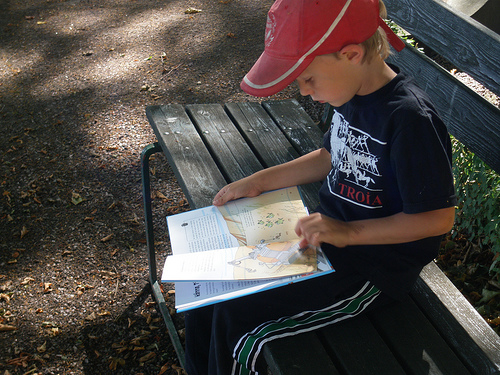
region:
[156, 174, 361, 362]
Book in a boys hands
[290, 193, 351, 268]
Hand on a book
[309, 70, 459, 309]
Shirt on a boy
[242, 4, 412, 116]
Red hat on a head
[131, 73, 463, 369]
Brown bench under a boy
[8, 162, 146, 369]
Leaves on the ground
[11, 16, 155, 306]
Brown leaf covered ground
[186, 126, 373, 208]
Arm on a boy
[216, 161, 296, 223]
Hand on a boy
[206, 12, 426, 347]
Boy on a bench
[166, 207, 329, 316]
a book holding by a boy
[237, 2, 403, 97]
a cap wearing by a small boy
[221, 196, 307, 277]
a art design inside the book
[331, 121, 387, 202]
design drawn in the shirt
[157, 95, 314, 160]
a wooden bench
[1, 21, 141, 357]
sand on the ground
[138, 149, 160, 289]
iron road holding the bench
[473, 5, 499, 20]
a small portion of tree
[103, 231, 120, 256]
flower fallen down from tree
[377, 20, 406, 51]
back lock of cap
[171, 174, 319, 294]
a book holding by boy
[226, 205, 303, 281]
an art design inside the books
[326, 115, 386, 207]
an design on the boys shirt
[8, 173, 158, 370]
sand on down of park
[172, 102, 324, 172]
wooden bench in the park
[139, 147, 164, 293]
a supporting stand of bench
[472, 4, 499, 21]
small portion of a tree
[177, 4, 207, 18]
a small stone in the sand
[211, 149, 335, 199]
hand of a small boy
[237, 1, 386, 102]
cap of the boy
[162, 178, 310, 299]
a book holding by the boy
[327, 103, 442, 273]
tshirt wearing by the boy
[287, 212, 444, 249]
left hand of the boy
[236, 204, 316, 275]
an art design in side the book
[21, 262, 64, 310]
flowers fallen from tree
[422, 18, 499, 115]
a wooden bench in the park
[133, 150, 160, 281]
supporting iron rod of the bench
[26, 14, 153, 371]
sand in the park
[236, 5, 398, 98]
cap wearing by the boy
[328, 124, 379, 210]
quotation on the boy tshirt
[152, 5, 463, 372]
young boy sitting on a bench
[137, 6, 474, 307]
young boy reading a book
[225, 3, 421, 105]
red hat with a white stripe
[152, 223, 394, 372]
black pants with white and green stripe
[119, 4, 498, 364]
an old wooden bench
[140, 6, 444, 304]
boy holding book open while he reads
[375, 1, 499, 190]
two boards make up back of bench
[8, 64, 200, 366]
leafs scattered on the ground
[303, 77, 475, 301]
black t-shirt with white and red on it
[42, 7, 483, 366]
boy reading a book in the park